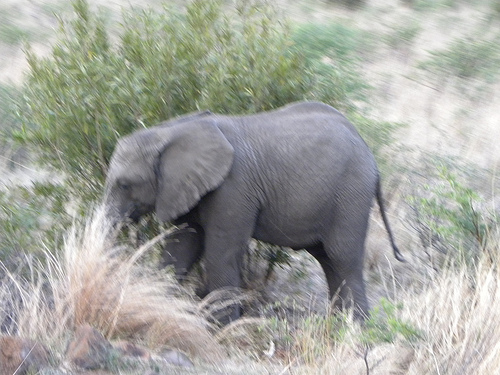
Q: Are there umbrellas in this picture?
A: No, there are no umbrellas.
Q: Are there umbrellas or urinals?
A: No, there are no umbrellas or urinals.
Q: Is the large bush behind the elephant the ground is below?
A: Yes, the shrub is behind the elephant.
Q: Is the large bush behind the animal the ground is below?
A: Yes, the shrub is behind the elephant.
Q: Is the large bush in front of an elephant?
A: No, the bush is behind an elephant.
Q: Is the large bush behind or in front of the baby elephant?
A: The bush is behind the elephant.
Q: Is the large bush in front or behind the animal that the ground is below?
A: The bush is behind the elephant.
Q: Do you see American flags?
A: No, there are no American flags.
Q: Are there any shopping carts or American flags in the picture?
A: No, there are no American flags or shopping carts.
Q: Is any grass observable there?
A: Yes, there is grass.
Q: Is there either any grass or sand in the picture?
A: Yes, there is grass.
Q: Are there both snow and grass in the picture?
A: No, there is grass but no snow.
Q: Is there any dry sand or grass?
A: Yes, there is dry grass.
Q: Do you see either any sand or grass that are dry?
A: Yes, the grass is dry.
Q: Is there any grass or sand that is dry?
A: Yes, the grass is dry.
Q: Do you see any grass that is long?
A: Yes, there is long grass.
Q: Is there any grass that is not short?
A: Yes, there is long grass.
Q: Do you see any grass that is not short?
A: Yes, there is long grass.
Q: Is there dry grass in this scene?
A: Yes, there is dry grass.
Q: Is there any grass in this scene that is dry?
A: Yes, there is dry grass.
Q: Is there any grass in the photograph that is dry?
A: Yes, there is grass that is dry.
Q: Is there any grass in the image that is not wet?
A: Yes, there is dry grass.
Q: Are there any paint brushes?
A: No, there are no paint brushes.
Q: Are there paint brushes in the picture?
A: No, there are no paint brushes.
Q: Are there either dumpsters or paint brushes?
A: No, there are no paint brushes or dumpsters.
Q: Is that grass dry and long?
A: Yes, the grass is dry and long.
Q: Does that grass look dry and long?
A: Yes, the grass is dry and long.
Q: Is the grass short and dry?
A: No, the grass is dry but long.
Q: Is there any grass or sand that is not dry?
A: No, there is grass but it is dry.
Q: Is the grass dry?
A: Yes, the grass is dry.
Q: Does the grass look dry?
A: Yes, the grass is dry.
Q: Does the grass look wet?
A: No, the grass is dry.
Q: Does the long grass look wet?
A: No, the grass is dry.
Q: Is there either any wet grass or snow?
A: No, there is grass but it is dry.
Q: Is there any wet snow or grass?
A: No, there is grass but it is dry.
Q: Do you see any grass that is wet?
A: No, there is grass but it is dry.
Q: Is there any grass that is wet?
A: No, there is grass but it is dry.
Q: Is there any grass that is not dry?
A: No, there is grass but it is dry.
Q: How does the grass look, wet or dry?
A: The grass is dry.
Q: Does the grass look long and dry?
A: Yes, the grass is long and dry.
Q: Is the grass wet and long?
A: No, the grass is long but dry.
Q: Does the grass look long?
A: Yes, the grass is long.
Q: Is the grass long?
A: Yes, the grass is long.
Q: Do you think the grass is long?
A: Yes, the grass is long.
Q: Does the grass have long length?
A: Yes, the grass is long.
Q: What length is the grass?
A: The grass is long.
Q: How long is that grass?
A: The grass is long.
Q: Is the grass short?
A: No, the grass is long.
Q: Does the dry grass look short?
A: No, the grass is long.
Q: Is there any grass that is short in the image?
A: No, there is grass but it is long.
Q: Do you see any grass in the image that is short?
A: No, there is grass but it is long.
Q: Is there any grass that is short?
A: No, there is grass but it is long.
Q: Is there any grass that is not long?
A: No, there is grass but it is long.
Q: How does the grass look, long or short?
A: The grass is long.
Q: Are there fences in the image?
A: No, there are no fences.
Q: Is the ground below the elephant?
A: Yes, the ground is below the elephant.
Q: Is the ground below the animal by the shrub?
A: Yes, the ground is below the elephant.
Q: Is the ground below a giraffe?
A: No, the ground is below the elephant.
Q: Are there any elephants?
A: Yes, there is an elephant.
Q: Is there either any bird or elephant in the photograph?
A: Yes, there is an elephant.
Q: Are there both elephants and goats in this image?
A: No, there is an elephant but no goats.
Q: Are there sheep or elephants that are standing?
A: Yes, the elephant is standing.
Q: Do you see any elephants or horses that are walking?
A: Yes, the elephant is walking.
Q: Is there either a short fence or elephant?
A: Yes, there is a short elephant.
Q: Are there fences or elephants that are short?
A: Yes, the elephant is short.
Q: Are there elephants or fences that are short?
A: Yes, the elephant is short.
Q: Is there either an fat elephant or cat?
A: Yes, there is a fat elephant.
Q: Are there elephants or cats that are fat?
A: Yes, the elephant is fat.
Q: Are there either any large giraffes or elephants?
A: Yes, there is a large elephant.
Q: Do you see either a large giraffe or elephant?
A: Yes, there is a large elephant.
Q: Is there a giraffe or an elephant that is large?
A: Yes, the elephant is large.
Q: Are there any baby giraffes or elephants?
A: Yes, there is a baby elephant.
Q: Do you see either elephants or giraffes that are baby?
A: Yes, the elephant is a baby.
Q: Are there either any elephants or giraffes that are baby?
A: Yes, the elephant is a baby.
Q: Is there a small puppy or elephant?
A: Yes, there is a small elephant.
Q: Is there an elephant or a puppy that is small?
A: Yes, the elephant is small.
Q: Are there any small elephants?
A: Yes, there is a small elephant.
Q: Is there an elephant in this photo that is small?
A: Yes, there is an elephant that is small.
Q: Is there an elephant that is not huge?
A: Yes, there is a small elephant.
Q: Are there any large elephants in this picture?
A: Yes, there is a large elephant.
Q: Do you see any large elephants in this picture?
A: Yes, there is a large elephant.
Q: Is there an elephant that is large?
A: Yes, there is an elephant that is large.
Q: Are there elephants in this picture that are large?
A: Yes, there is an elephant that is large.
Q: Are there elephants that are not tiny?
A: Yes, there is a large elephant.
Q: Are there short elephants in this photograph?
A: Yes, there is a short elephant.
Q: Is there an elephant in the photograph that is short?
A: Yes, there is an elephant that is short.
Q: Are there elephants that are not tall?
A: Yes, there is a short elephant.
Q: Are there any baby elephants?
A: Yes, there is a baby elephant.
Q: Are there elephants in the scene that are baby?
A: Yes, there is an elephant that is a baby.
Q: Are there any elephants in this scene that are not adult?
A: Yes, there is an baby elephant.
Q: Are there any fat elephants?
A: Yes, there is a fat elephant.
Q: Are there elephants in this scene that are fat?
A: Yes, there is an elephant that is fat.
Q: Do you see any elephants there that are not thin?
A: Yes, there is a fat elephant.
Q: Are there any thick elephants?
A: Yes, there is a thick elephant.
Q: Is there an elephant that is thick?
A: Yes, there is an elephant that is thick.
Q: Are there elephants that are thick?
A: Yes, there is an elephant that is thick.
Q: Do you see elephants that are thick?
A: Yes, there is an elephant that is thick.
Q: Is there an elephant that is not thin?
A: Yes, there is a thick elephant.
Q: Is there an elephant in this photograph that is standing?
A: Yes, there is an elephant that is standing.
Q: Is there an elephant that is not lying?
A: Yes, there is an elephant that is standing.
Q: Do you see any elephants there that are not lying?
A: Yes, there is an elephant that is standing .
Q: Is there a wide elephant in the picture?
A: Yes, there is a wide elephant.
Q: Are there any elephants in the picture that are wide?
A: Yes, there is an elephant that is wide.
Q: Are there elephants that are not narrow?
A: Yes, there is a wide elephant.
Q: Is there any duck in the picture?
A: No, there are no ducks.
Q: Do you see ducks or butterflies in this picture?
A: No, there are no ducks or butterflies.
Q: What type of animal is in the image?
A: The animal is an elephant.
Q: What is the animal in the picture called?
A: The animal is an elephant.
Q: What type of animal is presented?
A: The animal is an elephant.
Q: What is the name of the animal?
A: The animal is an elephant.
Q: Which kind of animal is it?
A: The animal is an elephant.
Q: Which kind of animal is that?
A: This is an elephant.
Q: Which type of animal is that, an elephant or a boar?
A: This is an elephant.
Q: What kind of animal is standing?
A: The animal is an elephant.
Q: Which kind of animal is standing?
A: The animal is an elephant.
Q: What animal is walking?
A: The animal is an elephant.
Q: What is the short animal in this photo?
A: The animal is an elephant.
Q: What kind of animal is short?
A: The animal is an elephant.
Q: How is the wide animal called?
A: The animal is an elephant.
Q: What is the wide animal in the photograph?
A: The animal is an elephant.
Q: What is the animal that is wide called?
A: The animal is an elephant.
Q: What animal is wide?
A: The animal is an elephant.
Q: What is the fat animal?
A: The animal is an elephant.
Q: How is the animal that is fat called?
A: The animal is an elephant.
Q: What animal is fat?
A: The animal is an elephant.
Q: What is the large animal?
A: The animal is an elephant.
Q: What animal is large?
A: The animal is an elephant.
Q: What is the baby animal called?
A: The animal is an elephant.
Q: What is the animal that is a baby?
A: The animal is an elephant.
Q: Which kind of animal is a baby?
A: The animal is an elephant.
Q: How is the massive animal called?
A: The animal is an elephant.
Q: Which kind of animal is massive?
A: The animal is an elephant.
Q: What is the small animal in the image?
A: The animal is an elephant.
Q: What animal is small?
A: The animal is an elephant.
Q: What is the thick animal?
A: The animal is an elephant.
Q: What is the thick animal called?
A: The animal is an elephant.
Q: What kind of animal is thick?
A: The animal is an elephant.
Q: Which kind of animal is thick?
A: The animal is an elephant.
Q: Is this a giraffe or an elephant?
A: This is an elephant.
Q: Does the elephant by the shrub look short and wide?
A: Yes, the elephant is short and wide.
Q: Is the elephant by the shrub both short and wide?
A: Yes, the elephant is short and wide.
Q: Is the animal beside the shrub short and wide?
A: Yes, the elephant is short and wide.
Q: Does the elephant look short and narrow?
A: No, the elephant is short but wide.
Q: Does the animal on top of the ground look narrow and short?
A: No, the elephant is short but wide.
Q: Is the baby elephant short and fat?
A: Yes, the elephant is short and fat.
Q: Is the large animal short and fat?
A: Yes, the elephant is short and fat.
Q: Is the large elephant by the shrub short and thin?
A: No, the elephant is short but fat.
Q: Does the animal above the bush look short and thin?
A: No, the elephant is short but fat.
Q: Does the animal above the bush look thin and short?
A: No, the elephant is short but fat.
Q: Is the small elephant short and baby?
A: Yes, the elephant is short and baby.